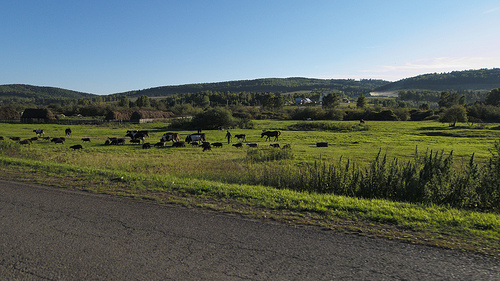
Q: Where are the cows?
A: In the field.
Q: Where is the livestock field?
A: Next to the road.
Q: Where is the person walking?
A: In the field with the cows.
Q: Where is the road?
A: Next to the pasture.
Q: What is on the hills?
A: Trees.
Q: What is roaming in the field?
A: Cows.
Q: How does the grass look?
A: Green and healthy.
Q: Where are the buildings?
A: Near the hillside.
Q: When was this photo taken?
A: When the cows were out to graze.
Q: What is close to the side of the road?
A: Plants.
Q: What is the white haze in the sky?
A: A cloud.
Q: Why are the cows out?
A: To graze.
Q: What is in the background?
A: Hills.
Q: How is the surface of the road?
A: Paved.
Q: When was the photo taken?
A: Daytime.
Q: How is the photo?
A: Clear.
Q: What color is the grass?
A: Green.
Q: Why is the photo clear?
A: Its during the day.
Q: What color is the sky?
A: Blue and white.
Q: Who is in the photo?
A: A person.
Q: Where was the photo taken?
A: In the field.